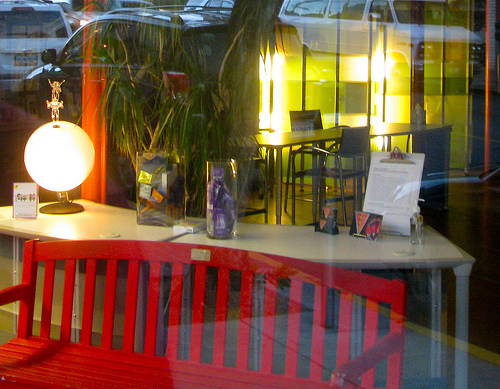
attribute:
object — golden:
[44, 74, 69, 119]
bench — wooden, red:
[2, 217, 407, 387]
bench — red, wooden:
[9, 223, 452, 387]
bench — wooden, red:
[17, 214, 415, 374]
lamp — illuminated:
[18, 116, 107, 193]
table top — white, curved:
[2, 185, 478, 290]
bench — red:
[24, 244, 328, 386]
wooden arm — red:
[336, 322, 417, 383]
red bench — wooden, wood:
[1, 239, 408, 387]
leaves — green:
[157, 103, 188, 137]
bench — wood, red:
[1, 238, 407, 383]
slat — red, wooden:
[205, 259, 230, 368]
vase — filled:
[128, 139, 188, 224]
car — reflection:
[0, 0, 70, 95]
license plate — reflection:
[15, 50, 41, 70]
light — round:
[19, 116, 96, 214]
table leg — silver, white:
[450, 261, 475, 387]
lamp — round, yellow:
[19, 117, 101, 194]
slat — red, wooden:
[46, 272, 125, 335]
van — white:
[2, 3, 75, 96]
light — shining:
[260, 44, 399, 151]